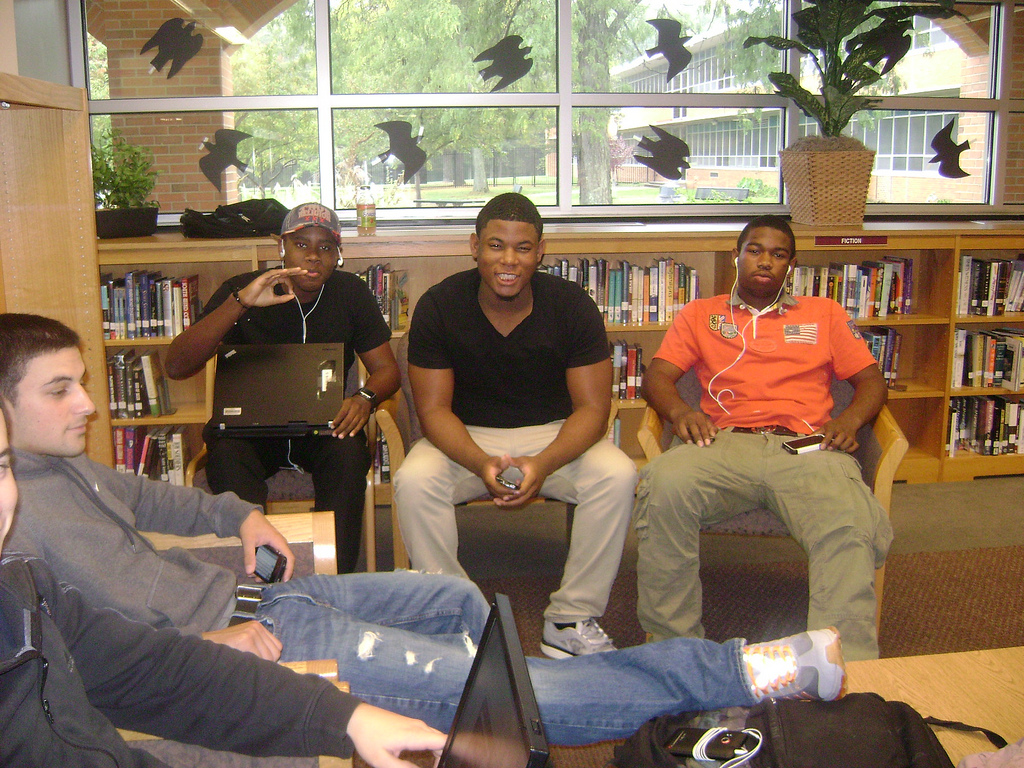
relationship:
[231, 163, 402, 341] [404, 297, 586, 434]
guy wearing shirt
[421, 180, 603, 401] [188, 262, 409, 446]
guy wearing shirt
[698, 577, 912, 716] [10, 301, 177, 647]
shoe of a man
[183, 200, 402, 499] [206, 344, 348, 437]
guy with laptop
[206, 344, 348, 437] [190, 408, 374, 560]
laptop on lap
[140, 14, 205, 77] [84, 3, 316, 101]
bat on window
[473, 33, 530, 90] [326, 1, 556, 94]
bat on window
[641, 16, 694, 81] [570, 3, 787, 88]
bat on window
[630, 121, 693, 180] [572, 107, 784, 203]
bat on window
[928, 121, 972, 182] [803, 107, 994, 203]
bat on window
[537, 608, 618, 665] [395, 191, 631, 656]
foot on man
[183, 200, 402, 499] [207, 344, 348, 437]
guy holding laptop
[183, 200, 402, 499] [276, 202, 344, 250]
guy wearing baseball cap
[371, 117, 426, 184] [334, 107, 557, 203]
bird taped to window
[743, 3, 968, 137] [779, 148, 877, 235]
plant in wicker basket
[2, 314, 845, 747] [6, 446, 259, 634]
man wearing jacket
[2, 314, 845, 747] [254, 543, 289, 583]
man holding cell phone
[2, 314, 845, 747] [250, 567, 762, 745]
man wearing jeans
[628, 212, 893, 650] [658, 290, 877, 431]
guy wearing shirt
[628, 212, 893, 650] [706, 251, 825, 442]
guy wearing earphones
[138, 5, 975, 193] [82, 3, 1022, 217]
birds on windows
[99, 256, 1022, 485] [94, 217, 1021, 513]
books on shelf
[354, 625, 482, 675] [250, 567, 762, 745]
marks on jeans